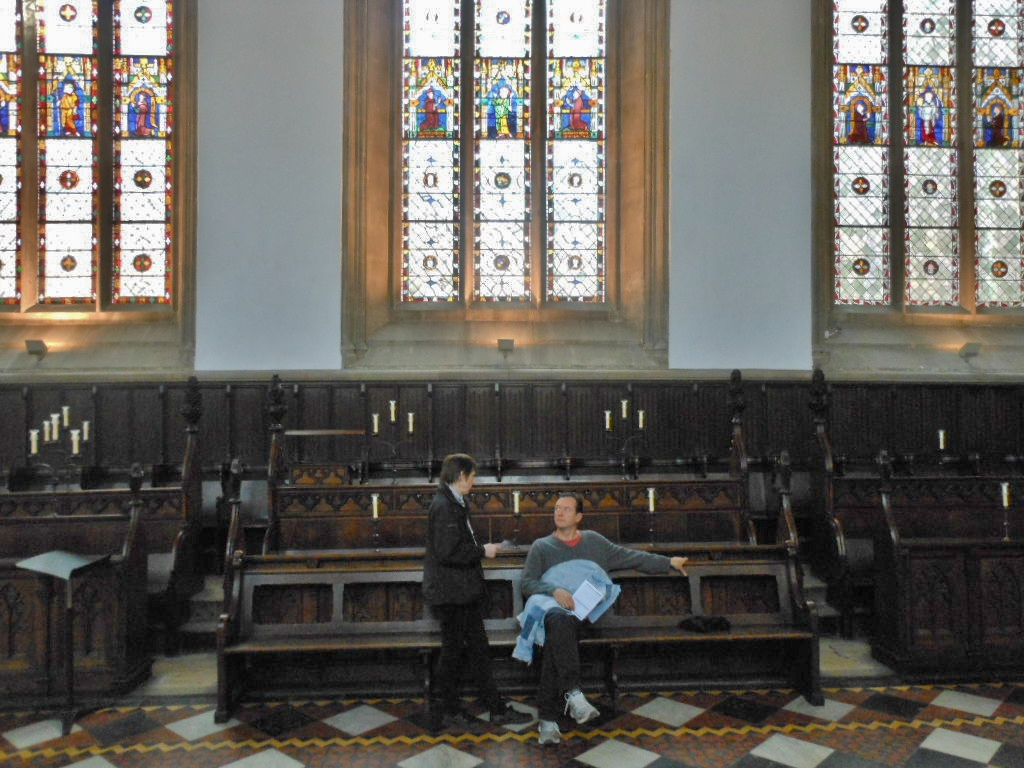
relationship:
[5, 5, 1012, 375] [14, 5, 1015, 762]
wall on building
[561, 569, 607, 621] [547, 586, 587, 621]
paper in man's hand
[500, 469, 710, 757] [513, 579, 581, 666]
man holding jacket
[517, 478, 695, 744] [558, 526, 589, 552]
man wearing undershirt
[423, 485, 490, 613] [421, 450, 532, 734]
jacket on man